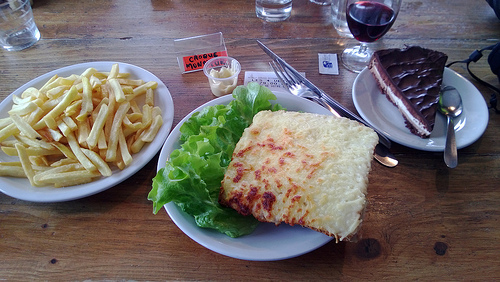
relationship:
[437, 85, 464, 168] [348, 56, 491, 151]
spoon resting on a plate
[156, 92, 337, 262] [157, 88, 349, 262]
plate of food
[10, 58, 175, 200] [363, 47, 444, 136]
plate with food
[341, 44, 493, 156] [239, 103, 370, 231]
plate with food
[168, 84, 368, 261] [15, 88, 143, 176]
plate with food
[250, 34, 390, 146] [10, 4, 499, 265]
knife on table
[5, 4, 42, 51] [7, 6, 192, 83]
bottle on table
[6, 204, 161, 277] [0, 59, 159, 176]
table with food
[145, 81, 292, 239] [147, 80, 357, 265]
lettuce on plate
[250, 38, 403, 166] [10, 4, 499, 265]
metal fork on table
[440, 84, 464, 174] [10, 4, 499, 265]
spoon on table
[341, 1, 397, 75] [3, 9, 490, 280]
glass on table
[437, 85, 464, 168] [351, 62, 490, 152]
spoon on plate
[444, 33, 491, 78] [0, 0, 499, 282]
black wire has table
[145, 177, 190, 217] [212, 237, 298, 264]
lettuce on plate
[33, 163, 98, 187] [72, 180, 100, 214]
french fry on plate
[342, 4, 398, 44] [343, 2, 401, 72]
beer in glass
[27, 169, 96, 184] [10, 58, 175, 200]
french fry on plate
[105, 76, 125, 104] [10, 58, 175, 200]
french fry on plate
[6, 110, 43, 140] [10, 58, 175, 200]
french fry on plate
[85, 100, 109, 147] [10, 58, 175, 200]
french fry on plate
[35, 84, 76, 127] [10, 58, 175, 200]
french fry on plate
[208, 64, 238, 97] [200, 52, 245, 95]
condiment in small container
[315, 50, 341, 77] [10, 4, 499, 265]
salt package on table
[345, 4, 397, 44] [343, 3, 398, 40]
wine in glass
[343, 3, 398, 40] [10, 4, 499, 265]
glass on table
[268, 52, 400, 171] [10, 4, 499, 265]
fork on table